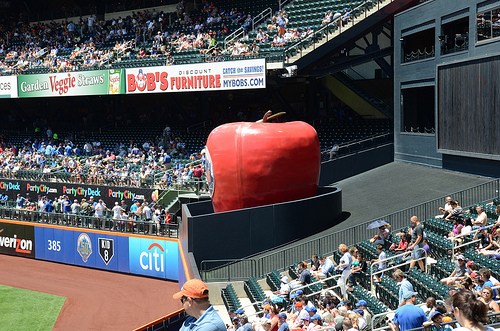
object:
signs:
[124, 58, 266, 95]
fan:
[172, 277, 228, 331]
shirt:
[176, 304, 227, 331]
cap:
[172, 278, 210, 300]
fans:
[404, 215, 426, 275]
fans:
[208, 35, 217, 58]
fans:
[164, 209, 173, 235]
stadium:
[0, 0, 500, 331]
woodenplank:
[437, 55, 500, 156]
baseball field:
[0, 254, 184, 331]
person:
[445, 200, 465, 223]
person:
[392, 289, 432, 331]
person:
[444, 288, 499, 331]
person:
[390, 268, 413, 307]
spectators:
[264, 275, 292, 304]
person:
[471, 206, 488, 226]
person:
[424, 295, 441, 318]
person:
[335, 243, 356, 302]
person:
[112, 202, 127, 232]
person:
[263, 308, 281, 331]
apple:
[203, 109, 321, 213]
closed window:
[400, 77, 436, 135]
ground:
[200, 160, 500, 282]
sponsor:
[0, 222, 35, 259]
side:
[0, 0, 396, 118]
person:
[313, 255, 335, 282]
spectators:
[287, 302, 309, 329]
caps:
[261, 304, 272, 310]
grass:
[0, 282, 68, 331]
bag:
[200, 110, 322, 213]